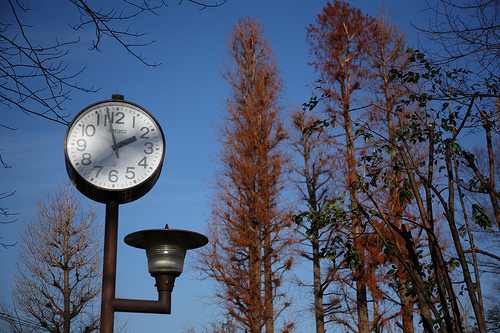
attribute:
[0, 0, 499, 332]
sky — blue, clear, rich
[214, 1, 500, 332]
trees — brown, bare, green, tall, leafy, thin, skinny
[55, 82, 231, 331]
clock — displaying, white, round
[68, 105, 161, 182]
face — white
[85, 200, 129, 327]
post — angled, dark, metal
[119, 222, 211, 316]
light — off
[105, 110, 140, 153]
hands — black